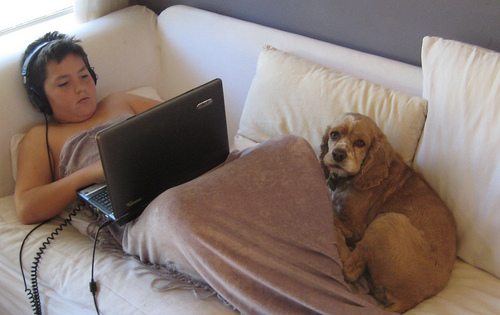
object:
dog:
[317, 113, 466, 315]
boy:
[11, 31, 167, 225]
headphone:
[22, 34, 98, 116]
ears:
[27, 87, 51, 114]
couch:
[0, 5, 499, 315]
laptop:
[75, 78, 235, 229]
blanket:
[56, 110, 404, 315]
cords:
[167, 213, 201, 249]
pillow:
[236, 44, 431, 171]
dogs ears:
[351, 138, 369, 148]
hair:
[19, 31, 97, 115]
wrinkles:
[357, 82, 367, 114]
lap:
[148, 188, 206, 231]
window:
[0, 0, 79, 33]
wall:
[135, 0, 500, 68]